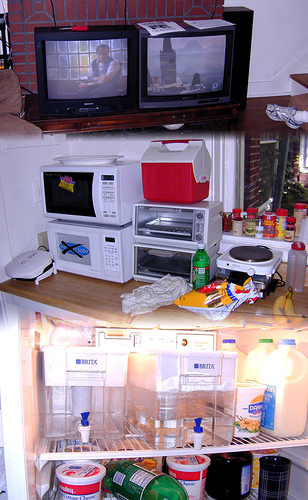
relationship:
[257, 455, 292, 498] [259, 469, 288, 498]
mug with design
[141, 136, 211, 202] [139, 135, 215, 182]
cooler has lid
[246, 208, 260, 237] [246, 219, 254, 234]
bottle of oregano